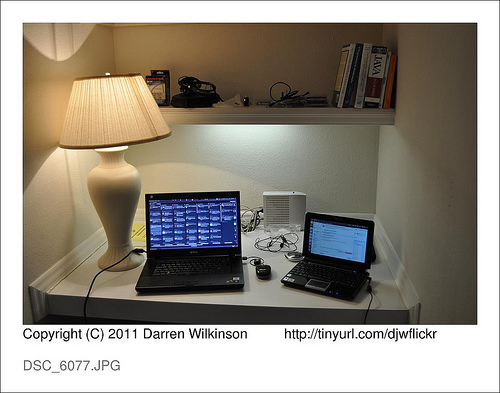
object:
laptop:
[133, 191, 245, 292]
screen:
[148, 197, 240, 249]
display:
[157, 203, 223, 242]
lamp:
[55, 70, 174, 272]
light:
[186, 122, 319, 140]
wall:
[22, 24, 477, 326]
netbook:
[282, 212, 375, 303]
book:
[334, 42, 356, 111]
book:
[365, 44, 386, 106]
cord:
[82, 247, 144, 326]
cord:
[362, 274, 373, 325]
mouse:
[253, 264, 272, 279]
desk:
[23, 213, 426, 325]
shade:
[23, 24, 131, 195]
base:
[88, 147, 146, 274]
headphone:
[178, 76, 221, 97]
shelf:
[112, 25, 399, 127]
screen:
[308, 219, 369, 262]